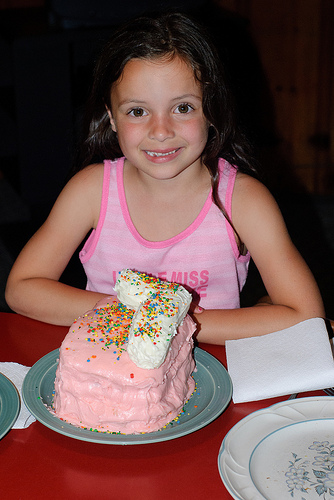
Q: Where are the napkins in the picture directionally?
A: Right.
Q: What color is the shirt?
A: Pink.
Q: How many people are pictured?
A: One.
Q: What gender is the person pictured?
A: Female.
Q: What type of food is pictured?
A: Cake.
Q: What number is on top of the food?
A: Seven.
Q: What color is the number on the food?
A: White.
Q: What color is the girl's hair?
A: Black.